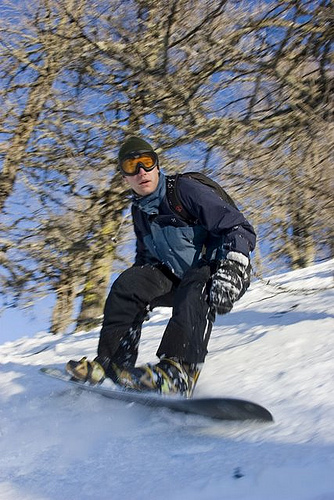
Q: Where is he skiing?
A: A hill.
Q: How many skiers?
A: One.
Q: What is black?
A: Snow suit.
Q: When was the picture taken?
A: Daytime.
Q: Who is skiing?
A: Man.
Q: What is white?
A: Snow.